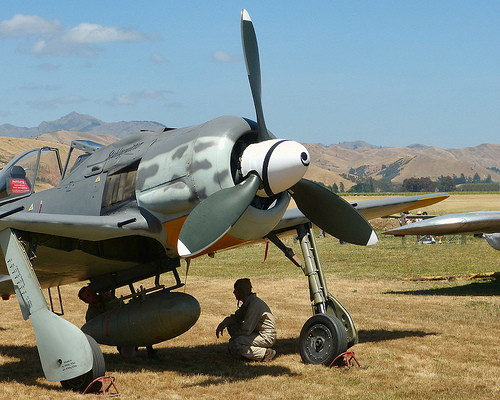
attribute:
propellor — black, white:
[173, 8, 378, 260]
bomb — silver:
[70, 273, 220, 383]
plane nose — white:
[238, 135, 313, 202]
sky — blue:
[2, 2, 498, 142]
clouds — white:
[1, 3, 153, 65]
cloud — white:
[31, 19, 162, 57]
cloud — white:
[1, 12, 68, 40]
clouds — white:
[214, 50, 241, 65]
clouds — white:
[62, 24, 158, 50]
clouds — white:
[2, 11, 64, 35]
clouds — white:
[109, 88, 164, 106]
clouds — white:
[21, 84, 61, 91]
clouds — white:
[56, 20, 196, 61]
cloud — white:
[2, 12, 62, 39]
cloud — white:
[57, 23, 161, 40]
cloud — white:
[28, 37, 99, 58]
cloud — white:
[209, 47, 238, 62]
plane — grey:
[26, 53, 408, 358]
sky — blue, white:
[0, 0, 495, 170]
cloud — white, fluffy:
[7, 4, 199, 92]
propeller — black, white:
[174, 7, 384, 259]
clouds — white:
[0, 11, 234, 112]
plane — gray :
[21, 0, 385, 387]